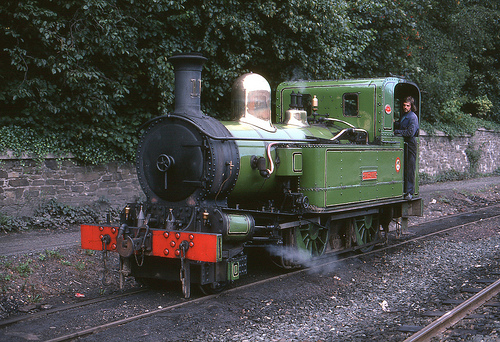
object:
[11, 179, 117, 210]
stone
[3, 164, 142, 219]
wall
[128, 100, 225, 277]
front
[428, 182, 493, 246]
track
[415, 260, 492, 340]
track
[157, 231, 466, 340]
ground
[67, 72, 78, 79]
leaves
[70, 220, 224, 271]
bumper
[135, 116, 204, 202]
circle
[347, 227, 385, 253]
wheels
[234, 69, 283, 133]
part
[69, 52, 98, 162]
trees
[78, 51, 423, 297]
engine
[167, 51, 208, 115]
smoke stack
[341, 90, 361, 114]
window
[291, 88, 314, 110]
window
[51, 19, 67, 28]
leaves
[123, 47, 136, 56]
leaves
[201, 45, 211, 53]
leaves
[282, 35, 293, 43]
leaves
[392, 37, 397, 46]
leaves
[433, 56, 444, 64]
leaves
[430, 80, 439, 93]
leaves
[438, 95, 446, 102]
leaves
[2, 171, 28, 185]
brick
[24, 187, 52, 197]
brick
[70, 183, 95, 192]
brick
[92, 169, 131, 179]
brick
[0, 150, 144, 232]
brick wall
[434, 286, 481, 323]
track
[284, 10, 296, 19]
leaves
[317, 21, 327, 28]
leaves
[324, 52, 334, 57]
leaves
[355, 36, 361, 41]
leaves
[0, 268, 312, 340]
track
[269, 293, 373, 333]
ballast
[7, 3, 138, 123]
tree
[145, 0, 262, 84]
tree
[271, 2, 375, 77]
tree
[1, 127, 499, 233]
fence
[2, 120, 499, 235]
wall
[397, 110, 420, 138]
shirt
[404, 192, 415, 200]
shoes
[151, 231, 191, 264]
sticker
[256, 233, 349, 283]
smoke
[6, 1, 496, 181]
bushes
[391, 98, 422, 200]
man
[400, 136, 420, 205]
jeans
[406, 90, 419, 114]
man's hair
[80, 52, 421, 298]
locomotive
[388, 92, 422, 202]
engineer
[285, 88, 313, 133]
engine's whistle